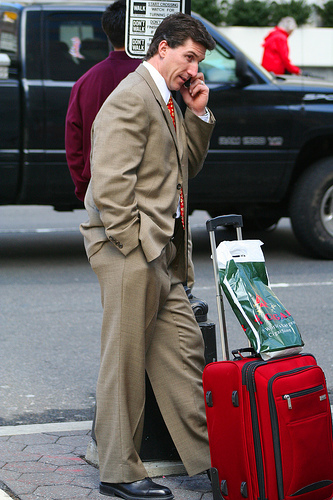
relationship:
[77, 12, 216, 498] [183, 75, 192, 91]
man talking on cellphone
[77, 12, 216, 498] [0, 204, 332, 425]
man beside street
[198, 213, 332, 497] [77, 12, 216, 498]
luggage in front of man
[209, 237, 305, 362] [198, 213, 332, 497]
shopping bag on top of luggage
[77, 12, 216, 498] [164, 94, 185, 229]
man wearing tie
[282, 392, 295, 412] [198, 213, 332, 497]
zipper on front of luggage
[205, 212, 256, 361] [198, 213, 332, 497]
handle on top of luggage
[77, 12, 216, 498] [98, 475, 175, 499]
man has right shoe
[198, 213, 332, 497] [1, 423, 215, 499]
luggage on top of sidewalk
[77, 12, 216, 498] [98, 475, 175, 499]
man wearing right shoe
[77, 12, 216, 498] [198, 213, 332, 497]
man standing behind luggage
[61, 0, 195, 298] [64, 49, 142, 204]
man wearing shirt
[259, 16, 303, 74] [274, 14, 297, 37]
woman has hair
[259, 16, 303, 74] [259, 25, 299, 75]
woman wearing jacket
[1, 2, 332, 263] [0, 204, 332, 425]
truck driving on street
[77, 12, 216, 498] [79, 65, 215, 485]
man wearing suit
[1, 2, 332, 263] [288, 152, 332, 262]
truck has tire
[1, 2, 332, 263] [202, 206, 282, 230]
truck has tire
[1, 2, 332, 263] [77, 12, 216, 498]
truck behind man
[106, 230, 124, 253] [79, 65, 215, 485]
buttons on side of suit